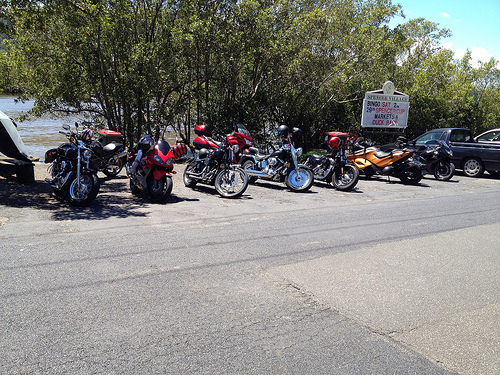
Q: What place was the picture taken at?
A: It was taken at the pavement.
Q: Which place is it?
A: It is a pavement.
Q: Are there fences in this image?
A: No, there are no fences.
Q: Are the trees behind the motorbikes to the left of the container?
A: Yes, the trees are behind the motorbikes.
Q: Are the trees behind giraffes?
A: No, the trees are behind the motorbikes.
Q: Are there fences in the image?
A: No, there are no fences.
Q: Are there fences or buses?
A: No, there are no fences or buses.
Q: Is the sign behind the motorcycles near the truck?
A: Yes, the sign is behind the motorbikes.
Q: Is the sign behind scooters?
A: No, the sign is behind the motorbikes.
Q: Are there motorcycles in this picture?
A: Yes, there is a motorcycle.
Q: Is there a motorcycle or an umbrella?
A: Yes, there is a motorcycle.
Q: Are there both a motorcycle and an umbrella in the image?
A: No, there is a motorcycle but no umbrellas.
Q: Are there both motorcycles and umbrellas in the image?
A: No, there is a motorcycle but no umbrellas.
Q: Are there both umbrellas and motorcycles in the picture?
A: No, there is a motorcycle but no umbrellas.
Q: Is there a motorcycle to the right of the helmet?
A: Yes, there is a motorcycle to the right of the helmet.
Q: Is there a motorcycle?
A: Yes, there are motorcycles.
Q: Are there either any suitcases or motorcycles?
A: Yes, there are motorcycles.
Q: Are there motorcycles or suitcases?
A: Yes, there are motorcycles.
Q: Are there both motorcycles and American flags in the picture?
A: No, there are motorcycles but no American flags.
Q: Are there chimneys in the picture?
A: No, there are no chimneys.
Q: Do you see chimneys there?
A: No, there are no chimneys.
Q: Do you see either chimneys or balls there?
A: No, there are no chimneys or balls.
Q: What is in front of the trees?
A: The motorbikes are in front of the trees.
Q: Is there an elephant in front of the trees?
A: No, there are motorcycles in front of the trees.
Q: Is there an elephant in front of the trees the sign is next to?
A: No, there are motorcycles in front of the trees.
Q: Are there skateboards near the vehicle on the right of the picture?
A: No, there are motorcycles near the truck.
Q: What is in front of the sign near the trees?
A: The motorcycles are in front of the sign.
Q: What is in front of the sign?
A: The motorcycles are in front of the sign.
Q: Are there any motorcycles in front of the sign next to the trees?
A: Yes, there are motorcycles in front of the sign.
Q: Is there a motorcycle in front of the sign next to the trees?
A: Yes, there are motorcycles in front of the sign.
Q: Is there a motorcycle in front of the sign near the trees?
A: Yes, there are motorcycles in front of the sign.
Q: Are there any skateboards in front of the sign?
A: No, there are motorcycles in front of the sign.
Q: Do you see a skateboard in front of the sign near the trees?
A: No, there are motorcycles in front of the sign.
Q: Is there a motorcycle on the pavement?
A: Yes, there are motorcycles on the pavement.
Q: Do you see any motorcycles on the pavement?
A: Yes, there are motorcycles on the pavement.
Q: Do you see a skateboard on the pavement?
A: No, there are motorcycles on the pavement.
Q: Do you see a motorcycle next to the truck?
A: Yes, there are motorcycles next to the truck.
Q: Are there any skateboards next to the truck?
A: No, there are motorcycles next to the truck.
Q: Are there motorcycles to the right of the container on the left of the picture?
A: Yes, there are motorcycles to the right of the container.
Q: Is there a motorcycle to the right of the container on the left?
A: Yes, there are motorcycles to the right of the container.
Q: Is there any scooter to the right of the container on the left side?
A: No, there are motorcycles to the right of the container.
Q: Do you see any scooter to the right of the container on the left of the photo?
A: No, there are motorcycles to the right of the container.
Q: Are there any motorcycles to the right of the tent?
A: Yes, there are motorcycles to the right of the tent.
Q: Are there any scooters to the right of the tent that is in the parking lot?
A: No, there are motorcycles to the right of the tent.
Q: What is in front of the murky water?
A: The motorcycles are in front of the water.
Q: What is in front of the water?
A: The motorcycles are in front of the water.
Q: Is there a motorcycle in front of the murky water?
A: Yes, there are motorcycles in front of the water.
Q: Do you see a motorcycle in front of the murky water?
A: Yes, there are motorcycles in front of the water.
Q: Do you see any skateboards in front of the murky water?
A: No, there are motorcycles in front of the water.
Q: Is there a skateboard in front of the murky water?
A: No, there are motorcycles in front of the water.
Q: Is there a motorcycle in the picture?
A: Yes, there is a motorcycle.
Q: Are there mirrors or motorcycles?
A: Yes, there is a motorcycle.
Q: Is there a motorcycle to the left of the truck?
A: Yes, there is a motorcycle to the left of the truck.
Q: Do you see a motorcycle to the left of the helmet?
A: Yes, there is a motorcycle to the left of the helmet.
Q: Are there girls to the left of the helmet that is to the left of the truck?
A: No, there is a motorcycle to the left of the helmet.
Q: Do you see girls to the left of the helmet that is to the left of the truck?
A: No, there is a motorcycle to the left of the helmet.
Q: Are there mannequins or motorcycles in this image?
A: Yes, there is a motorcycle.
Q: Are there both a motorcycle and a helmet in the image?
A: Yes, there are both a motorcycle and a helmet.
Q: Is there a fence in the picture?
A: No, there are no fences.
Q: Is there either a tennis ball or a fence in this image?
A: No, there are no fences or tennis balls.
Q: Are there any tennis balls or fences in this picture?
A: No, there are no fences or tennis balls.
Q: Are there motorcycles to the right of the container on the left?
A: Yes, there is a motorcycle to the right of the container.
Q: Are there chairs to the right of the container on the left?
A: No, there is a motorcycle to the right of the container.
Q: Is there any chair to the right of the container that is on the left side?
A: No, there is a motorcycle to the right of the container.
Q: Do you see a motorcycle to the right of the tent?
A: Yes, there is a motorcycle to the right of the tent.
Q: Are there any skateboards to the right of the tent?
A: No, there is a motorcycle to the right of the tent.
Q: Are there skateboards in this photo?
A: No, there are no skateboards.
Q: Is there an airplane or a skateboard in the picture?
A: No, there are no skateboards or airplanes.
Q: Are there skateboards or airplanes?
A: No, there are no skateboards or airplanes.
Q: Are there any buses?
A: No, there are no buses.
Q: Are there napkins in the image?
A: No, there are no napkins.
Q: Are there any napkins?
A: No, there are no napkins.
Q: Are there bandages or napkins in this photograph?
A: No, there are no napkins or bandages.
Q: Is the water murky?
A: Yes, the water is murky.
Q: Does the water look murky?
A: Yes, the water is murky.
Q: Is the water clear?
A: No, the water is murky.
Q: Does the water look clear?
A: No, the water is murky.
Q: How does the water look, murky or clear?
A: The water is murky.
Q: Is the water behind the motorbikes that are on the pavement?
A: Yes, the water is behind the motorbikes.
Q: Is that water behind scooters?
A: No, the water is behind the motorbikes.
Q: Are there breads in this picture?
A: No, there are no breads.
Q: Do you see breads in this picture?
A: No, there are no breads.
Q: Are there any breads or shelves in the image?
A: No, there are no breads or shelves.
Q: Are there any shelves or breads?
A: No, there are no breads or shelves.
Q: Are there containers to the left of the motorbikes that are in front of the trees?
A: Yes, there is a container to the left of the motorcycles.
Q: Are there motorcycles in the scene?
A: Yes, there is a motorcycle.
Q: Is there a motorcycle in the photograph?
A: Yes, there is a motorcycle.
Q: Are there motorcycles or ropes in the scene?
A: Yes, there is a motorcycle.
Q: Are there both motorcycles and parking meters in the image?
A: No, there is a motorcycle but no parking meters.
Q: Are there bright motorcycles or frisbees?
A: Yes, there is a bright motorcycle.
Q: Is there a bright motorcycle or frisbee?
A: Yes, there is a bright motorcycle.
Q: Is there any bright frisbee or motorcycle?
A: Yes, there is a bright motorcycle.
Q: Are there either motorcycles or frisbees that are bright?
A: Yes, the motorcycle is bright.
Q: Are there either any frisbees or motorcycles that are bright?
A: Yes, the motorcycle is bright.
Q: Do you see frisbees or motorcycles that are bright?
A: Yes, the motorcycle is bright.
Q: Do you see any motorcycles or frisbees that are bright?
A: Yes, the motorcycle is bright.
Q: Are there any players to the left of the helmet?
A: No, there is a motorcycle to the left of the helmet.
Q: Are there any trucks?
A: Yes, there is a truck.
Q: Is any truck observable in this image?
A: Yes, there is a truck.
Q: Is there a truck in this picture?
A: Yes, there is a truck.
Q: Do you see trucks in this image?
A: Yes, there is a truck.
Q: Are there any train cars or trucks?
A: Yes, there is a truck.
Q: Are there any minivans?
A: No, there are no minivans.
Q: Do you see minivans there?
A: No, there are no minivans.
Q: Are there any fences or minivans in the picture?
A: No, there are no minivans or fences.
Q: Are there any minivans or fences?
A: No, there are no minivans or fences.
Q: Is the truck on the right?
A: Yes, the truck is on the right of the image.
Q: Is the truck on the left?
A: No, the truck is on the right of the image.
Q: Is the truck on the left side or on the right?
A: The truck is on the right of the image.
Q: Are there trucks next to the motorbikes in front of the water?
A: Yes, there is a truck next to the motorbikes.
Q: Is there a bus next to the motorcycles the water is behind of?
A: No, there is a truck next to the motorbikes.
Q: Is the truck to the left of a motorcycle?
A: No, the truck is to the right of a motorcycle.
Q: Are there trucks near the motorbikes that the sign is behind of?
A: Yes, there is a truck near the motorbikes.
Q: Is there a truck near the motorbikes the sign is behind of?
A: Yes, there is a truck near the motorbikes.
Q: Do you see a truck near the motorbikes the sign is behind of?
A: Yes, there is a truck near the motorbikes.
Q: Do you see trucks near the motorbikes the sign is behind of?
A: Yes, there is a truck near the motorbikes.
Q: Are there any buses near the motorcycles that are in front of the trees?
A: No, there is a truck near the motorcycles.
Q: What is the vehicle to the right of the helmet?
A: The vehicle is a truck.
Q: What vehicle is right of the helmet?
A: The vehicle is a truck.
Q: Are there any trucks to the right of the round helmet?
A: Yes, there is a truck to the right of the helmet.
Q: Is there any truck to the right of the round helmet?
A: Yes, there is a truck to the right of the helmet.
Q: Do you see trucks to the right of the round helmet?
A: Yes, there is a truck to the right of the helmet.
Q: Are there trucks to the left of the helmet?
A: No, the truck is to the right of the helmet.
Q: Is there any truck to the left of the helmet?
A: No, the truck is to the right of the helmet.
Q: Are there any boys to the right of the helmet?
A: No, there is a truck to the right of the helmet.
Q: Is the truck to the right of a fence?
A: No, the truck is to the right of the helmet.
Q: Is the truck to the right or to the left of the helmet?
A: The truck is to the right of the helmet.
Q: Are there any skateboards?
A: No, there are no skateboards.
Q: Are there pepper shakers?
A: No, there are no pepper shakers.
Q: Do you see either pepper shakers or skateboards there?
A: No, there are no pepper shakers or skateboards.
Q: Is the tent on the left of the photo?
A: Yes, the tent is on the left of the image.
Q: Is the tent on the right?
A: No, the tent is on the left of the image.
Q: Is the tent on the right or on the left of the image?
A: The tent is on the left of the image.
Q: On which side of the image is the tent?
A: The tent is on the left of the image.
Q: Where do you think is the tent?
A: The tent is in the parking lot.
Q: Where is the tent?
A: The tent is in the parking lot.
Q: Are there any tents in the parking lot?
A: Yes, there is a tent in the parking lot.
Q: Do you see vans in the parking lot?
A: No, there is a tent in the parking lot.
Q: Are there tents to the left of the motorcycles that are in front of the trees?
A: Yes, there is a tent to the left of the motorbikes.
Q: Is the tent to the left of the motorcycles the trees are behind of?
A: Yes, the tent is to the left of the motorbikes.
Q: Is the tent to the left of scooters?
A: No, the tent is to the left of the motorbikes.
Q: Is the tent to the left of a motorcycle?
A: Yes, the tent is to the left of a motorcycle.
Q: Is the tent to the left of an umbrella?
A: No, the tent is to the left of a motorcycle.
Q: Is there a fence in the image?
A: No, there are no fences.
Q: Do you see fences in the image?
A: No, there are no fences.